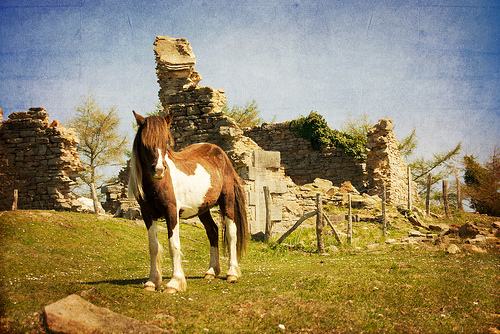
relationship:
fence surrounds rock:
[254, 162, 468, 245] [329, 154, 494, 247]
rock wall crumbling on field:
[4, 103, 76, 211] [2, 206, 495, 333]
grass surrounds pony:
[161, 260, 323, 307] [90, 86, 248, 284]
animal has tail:
[128, 110, 249, 294] [213, 160, 266, 301]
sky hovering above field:
[234, 10, 491, 124] [4, 197, 482, 322]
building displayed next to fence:
[0, 35, 417, 237] [405, 220, 498, 255]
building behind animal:
[153, 34, 427, 239] [128, 110, 249, 294]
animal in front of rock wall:
[128, 110, 249, 294] [1, 30, 426, 242]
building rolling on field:
[0, 35, 417, 237] [0, 200, 499, 334]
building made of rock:
[0, 35, 417, 237] [292, 182, 359, 222]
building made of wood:
[0, 35, 417, 237] [246, 179, 276, 236]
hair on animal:
[141, 115, 175, 151] [128, 110, 249, 294]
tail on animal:
[218, 174, 249, 263] [128, 110, 249, 294]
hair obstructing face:
[132, 120, 173, 150] [126, 109, 182, 197]